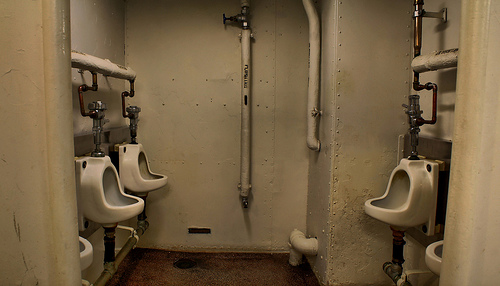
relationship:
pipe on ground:
[288, 228, 318, 269] [350, 136, 400, 188]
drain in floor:
[145, 243, 215, 275] [157, 248, 273, 279]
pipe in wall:
[304, 0, 325, 150] [330, 61, 377, 118]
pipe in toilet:
[399, 3, 449, 131] [359, 156, 435, 222]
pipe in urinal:
[97, 225, 124, 268] [108, 137, 173, 192]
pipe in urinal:
[97, 225, 124, 268] [77, 150, 151, 237]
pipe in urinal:
[97, 225, 124, 268] [77, 232, 102, 273]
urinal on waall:
[363, 155, 435, 231] [315, 36, 421, 276]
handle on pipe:
[218, 3, 251, 28] [236, 19, 257, 210]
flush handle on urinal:
[397, 102, 414, 111] [361, 147, 442, 238]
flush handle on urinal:
[100, 116, 111, 123] [62, 151, 147, 232]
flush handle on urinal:
[397, 102, 414, 111] [110, 134, 172, 197]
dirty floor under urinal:
[114, 247, 319, 283] [74, 140, 169, 230]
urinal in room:
[358, 153, 435, 231] [9, 9, 454, 283]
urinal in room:
[115, 134, 173, 194] [9, 9, 454, 283]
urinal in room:
[70, 154, 144, 226] [9, 9, 454, 283]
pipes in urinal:
[76, 68, 107, 156] [364, 156, 435, 227]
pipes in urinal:
[115, 79, 142, 142] [116, 139, 171, 191]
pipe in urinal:
[399, 0, 448, 131] [72, 150, 147, 223]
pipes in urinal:
[70, 48, 140, 78] [72, 150, 147, 223]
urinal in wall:
[358, 153, 435, 231] [3, 2, 76, 283]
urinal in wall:
[115, 141, 169, 194] [3, 2, 76, 283]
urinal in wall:
[70, 152, 142, 226] [3, 2, 76, 283]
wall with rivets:
[117, 0, 308, 260] [148, 66, 284, 125]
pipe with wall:
[221, 0, 254, 207] [131, 8, 302, 255]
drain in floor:
[171, 258, 203, 269] [109, 195, 387, 283]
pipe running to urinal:
[399, 0, 448, 131] [347, 144, 447, 253]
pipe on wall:
[221, 0, 254, 207] [125, 3, 315, 248]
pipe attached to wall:
[304, 11, 321, 150] [349, 47, 383, 136]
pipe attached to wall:
[288, 228, 318, 270] [294, 119, 352, 284]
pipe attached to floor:
[288, 228, 318, 270] [138, 227, 267, 284]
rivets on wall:
[143, 74, 284, 84] [131, 8, 302, 255]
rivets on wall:
[149, 97, 276, 110] [131, 8, 302, 255]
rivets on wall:
[322, 0, 345, 280] [336, 8, 414, 276]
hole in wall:
[183, 222, 218, 237] [125, 3, 315, 248]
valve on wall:
[212, 0, 265, 36] [125, 3, 315, 248]